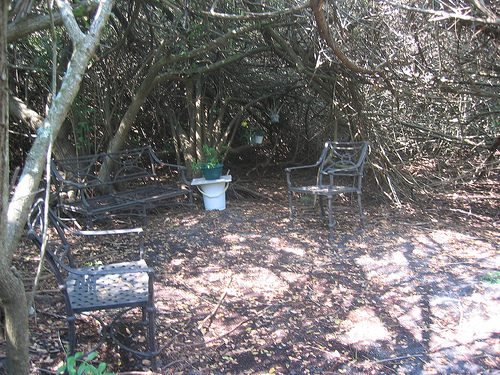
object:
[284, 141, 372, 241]
bench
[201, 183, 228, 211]
bucket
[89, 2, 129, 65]
trees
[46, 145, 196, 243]
metal bench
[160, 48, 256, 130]
trees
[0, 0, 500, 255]
canopy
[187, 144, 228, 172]
plant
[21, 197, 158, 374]
metal bench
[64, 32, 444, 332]
woods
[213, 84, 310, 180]
tree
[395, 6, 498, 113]
tree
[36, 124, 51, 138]
leaf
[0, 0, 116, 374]
tree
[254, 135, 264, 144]
bucket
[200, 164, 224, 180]
bucket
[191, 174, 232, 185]
board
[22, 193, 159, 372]
chair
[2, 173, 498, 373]
ground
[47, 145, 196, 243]
bench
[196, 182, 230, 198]
handle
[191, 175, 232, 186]
table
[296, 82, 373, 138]
trees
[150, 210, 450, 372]
shadows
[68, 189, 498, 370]
dirt clearing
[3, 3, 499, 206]
background